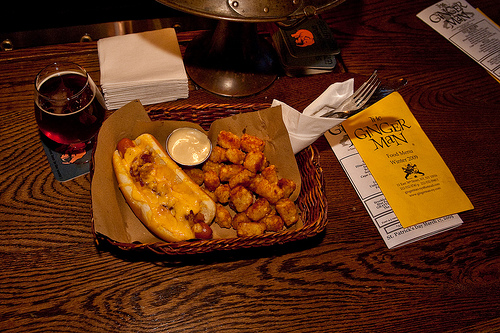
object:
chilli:
[137, 150, 157, 166]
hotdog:
[111, 132, 219, 245]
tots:
[165, 124, 214, 166]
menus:
[320, 89, 474, 253]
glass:
[34, 57, 108, 147]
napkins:
[93, 27, 191, 109]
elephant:
[291, 29, 314, 47]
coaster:
[277, 19, 343, 59]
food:
[234, 221, 267, 239]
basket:
[88, 99, 329, 257]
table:
[3, 16, 497, 331]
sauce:
[167, 128, 212, 164]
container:
[164, 126, 213, 166]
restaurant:
[353, 114, 412, 150]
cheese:
[153, 213, 188, 233]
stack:
[95, 29, 192, 107]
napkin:
[269, 77, 352, 156]